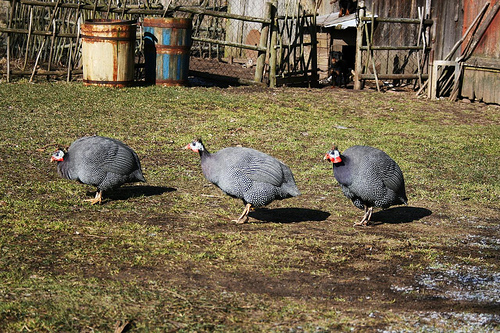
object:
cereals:
[469, 277, 494, 303]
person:
[182, 136, 307, 228]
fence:
[358, 1, 431, 92]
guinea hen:
[324, 140, 406, 222]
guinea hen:
[183, 133, 302, 225]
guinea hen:
[49, 134, 145, 207]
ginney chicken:
[324, 144, 406, 225]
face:
[319, 147, 340, 164]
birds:
[316, 142, 413, 230]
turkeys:
[324, 137, 414, 232]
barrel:
[143, 16, 192, 86]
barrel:
[77, 18, 132, 86]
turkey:
[317, 127, 422, 219]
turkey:
[180, 132, 306, 226]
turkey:
[39, 129, 142, 209]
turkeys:
[46, 129, 153, 211]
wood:
[462, 63, 496, 106]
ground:
[114, 248, 224, 303]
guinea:
[323, 143, 409, 228]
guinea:
[183, 136, 303, 226]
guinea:
[50, 134, 147, 208]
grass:
[2, 82, 47, 129]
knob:
[326, 143, 345, 152]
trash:
[144, 17, 191, 86]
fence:
[0, 0, 72, 78]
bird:
[40, 131, 152, 207]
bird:
[179, 132, 304, 227]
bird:
[317, 140, 409, 231]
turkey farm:
[2, 0, 499, 332]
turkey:
[183, 136, 300, 223]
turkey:
[325, 143, 409, 225]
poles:
[236, 0, 249, 62]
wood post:
[253, 2, 295, 97]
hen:
[316, 140, 416, 231]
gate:
[276, 6, 321, 88]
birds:
[47, 131, 152, 207]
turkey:
[49, 135, 144, 205]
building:
[436, 2, 495, 105]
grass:
[3, 192, 33, 272]